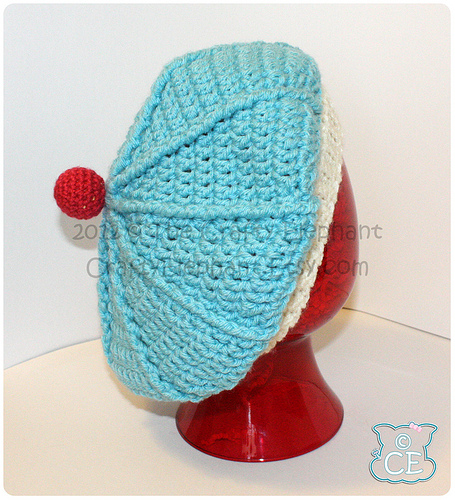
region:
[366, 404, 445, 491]
a logo in form of a big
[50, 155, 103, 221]
a red ball of yarn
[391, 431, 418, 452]
the copyright logo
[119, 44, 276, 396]
a cover made of green thread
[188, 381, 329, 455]
a red plastic base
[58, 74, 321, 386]
a cover made of red and green thread colors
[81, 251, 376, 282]
craft/elephant.Etsy.com web address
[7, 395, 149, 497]
beige surface table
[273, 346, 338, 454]
part of a red plastic object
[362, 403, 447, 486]
an outlined green color logo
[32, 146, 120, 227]
Red detail on a hat.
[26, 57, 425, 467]
Hat on a display.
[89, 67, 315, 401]
Blue hat on display.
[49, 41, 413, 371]
Crochet hat on the stand.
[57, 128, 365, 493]
Red hat stand.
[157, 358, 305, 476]
Reflection on the hat stand.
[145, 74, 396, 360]
White on the hat.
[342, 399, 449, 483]
Logo on the photo.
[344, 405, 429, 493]
CE written on the photo.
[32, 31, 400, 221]
Wall in the background.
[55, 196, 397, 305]
crafty elephant watermark across the photo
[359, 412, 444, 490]
CE copyright and symbol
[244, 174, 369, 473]
red mannequin head type display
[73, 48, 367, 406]
a handmade blue and white hat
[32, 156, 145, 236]
a red poof on a blue hat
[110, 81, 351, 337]
a blue knitted hat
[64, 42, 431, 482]
a handmade item for sale on etsy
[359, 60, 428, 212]
the white background of an item display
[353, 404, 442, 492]
the outline of an elephant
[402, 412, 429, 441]
a little pink bow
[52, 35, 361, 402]
hat is blue and white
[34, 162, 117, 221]
red piece of hat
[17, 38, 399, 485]
hat is on a mannequin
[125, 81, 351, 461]
holes in the hat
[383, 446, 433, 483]
white letters in picture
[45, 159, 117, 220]
part of hat is circular shaped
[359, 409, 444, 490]
the shape is blue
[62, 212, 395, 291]
the letters are gray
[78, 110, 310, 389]
lines are on hat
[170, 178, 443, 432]
the mannequin is see through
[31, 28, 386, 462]
a blue crocheted hat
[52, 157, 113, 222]
the ball on the hat is red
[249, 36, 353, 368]
the trim on the hat is white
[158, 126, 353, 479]
the maniquin is red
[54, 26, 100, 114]
the background is white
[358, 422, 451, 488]
a logo with a bow on it is in the corner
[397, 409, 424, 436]
the bow is pink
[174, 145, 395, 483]
the maniquin head is plastic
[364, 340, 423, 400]
the table is white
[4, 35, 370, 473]
this hat is handmade